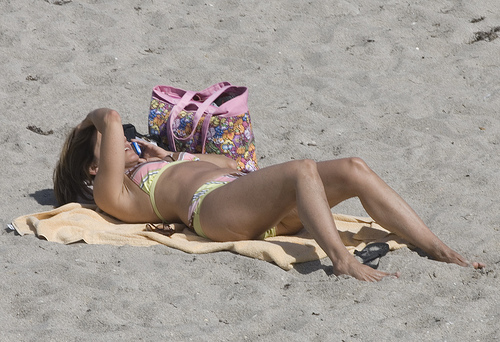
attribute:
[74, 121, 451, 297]
lady — lying, sunbathing, talking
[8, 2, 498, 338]
beach — sandy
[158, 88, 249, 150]
purse — pink, woman's, yellow, blue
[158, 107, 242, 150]
design — floral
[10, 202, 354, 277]
blanket — orange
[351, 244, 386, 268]
sandal — black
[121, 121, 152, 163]
phone — woman's, blue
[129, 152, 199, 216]
bathing suit — pink, green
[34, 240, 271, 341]
sand — grey, black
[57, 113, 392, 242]
woman — tanning, hot, lying, lying down, laying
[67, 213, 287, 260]
towel — orange, creme, bleached, yellow, peach, wrinkled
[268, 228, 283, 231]
vagina — her's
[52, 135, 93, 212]
hair — straight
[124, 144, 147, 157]
cellphone — blue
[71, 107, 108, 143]
hand — girl's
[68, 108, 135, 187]
head — girl's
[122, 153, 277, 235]
body — woman's, tan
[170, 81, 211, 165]
handles — pink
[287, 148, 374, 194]
knees — bent, woman's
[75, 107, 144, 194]
arm — bent